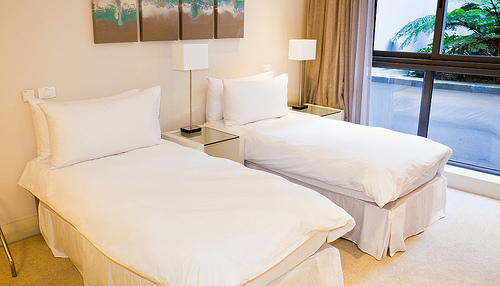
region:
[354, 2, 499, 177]
window partitioned into four areas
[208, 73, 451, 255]
a twin size bed with white linen in a hotel room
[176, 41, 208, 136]
modern style lamp with a rectangular shaped hood and long stem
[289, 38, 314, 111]
hotel lamp found on a night stand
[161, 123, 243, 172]
white nightstand situated between two twin beds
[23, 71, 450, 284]
two twin sized beds in a hotel room with a nightstand between them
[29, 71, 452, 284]
two beds, twin size decorated with white linen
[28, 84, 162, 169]
two large comfortable pillows found on a twin size hotel bed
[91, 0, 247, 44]
a painting separated on four different canvases hanging on a wall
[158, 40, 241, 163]
a lamp resting on a nightstand between two twin beds inside a hotel room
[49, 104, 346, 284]
the bed is white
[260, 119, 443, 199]
the bed is white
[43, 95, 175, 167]
the pillows are two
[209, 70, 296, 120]
the pillows are two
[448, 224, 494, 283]
the ground is carpeted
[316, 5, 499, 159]
the window is open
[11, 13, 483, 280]
the scene is a hotel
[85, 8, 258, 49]
the paintings are four on the wall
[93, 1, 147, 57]
the pianting is brown and green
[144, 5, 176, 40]
the painting is brown and green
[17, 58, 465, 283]
Two beds in a hotel room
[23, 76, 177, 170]
White pillow on bed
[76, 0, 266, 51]
Paintings on hotel room wall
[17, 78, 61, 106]
lighting controls on hotel wall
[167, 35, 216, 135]
Lamp with white shade on end table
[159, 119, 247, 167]
End table between two beds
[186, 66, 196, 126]
metal pole on lamp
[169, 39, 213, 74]
white shade on lamp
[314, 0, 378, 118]
curtains in hotel room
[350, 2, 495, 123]
Window in hotel room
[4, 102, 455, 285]
two half beds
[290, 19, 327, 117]
a tall lamp with a white shade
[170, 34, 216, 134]
a bed side lamp on a table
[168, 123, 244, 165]
a bed side table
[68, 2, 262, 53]
four pictures hanging on a wall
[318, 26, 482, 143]
a large window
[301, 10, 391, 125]
long curtains covering a window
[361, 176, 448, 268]
a white bed skirt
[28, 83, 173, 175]
two white pillows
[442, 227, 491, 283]
white carpeting on a floor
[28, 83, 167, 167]
White pillows on a single bed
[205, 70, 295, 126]
Two pillows lying on a bed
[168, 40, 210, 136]
Square table lamp sitting on the nightstand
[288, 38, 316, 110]
Lamp sitting on the table beside the bed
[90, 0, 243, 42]
Decorative screenprint on the wall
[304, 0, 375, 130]
Beige curtains hanging in the window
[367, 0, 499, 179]
Large windows in the wall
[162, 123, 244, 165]
Nightstand between the beds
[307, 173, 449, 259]
Duster on a single bed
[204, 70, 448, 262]
Single bed in a hotel room